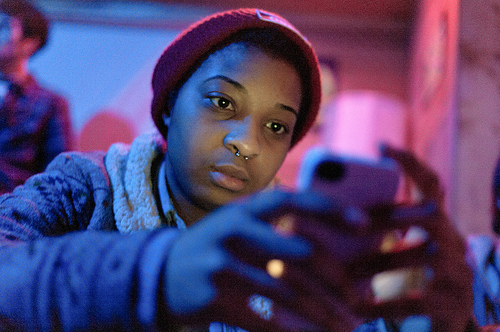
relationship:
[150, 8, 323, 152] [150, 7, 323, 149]
hat has fabric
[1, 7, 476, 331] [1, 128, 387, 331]
girl wearing a sweater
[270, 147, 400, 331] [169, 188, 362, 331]
phone in hand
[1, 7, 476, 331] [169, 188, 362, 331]
girl has a hand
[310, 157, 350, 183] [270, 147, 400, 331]
lens on back of phone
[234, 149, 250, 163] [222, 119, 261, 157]
ring in nose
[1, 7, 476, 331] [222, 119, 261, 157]
girl has a nose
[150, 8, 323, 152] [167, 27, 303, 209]
hat on head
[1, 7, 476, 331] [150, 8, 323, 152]
girl wearing a hat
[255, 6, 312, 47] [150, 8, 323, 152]
label on top of hat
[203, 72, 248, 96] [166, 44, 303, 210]
eyebrow on face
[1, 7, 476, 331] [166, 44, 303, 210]
girl has a face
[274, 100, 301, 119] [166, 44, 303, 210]
eyebrow on face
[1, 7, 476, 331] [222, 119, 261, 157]
person has a nose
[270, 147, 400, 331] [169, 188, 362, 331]
cell phone in hand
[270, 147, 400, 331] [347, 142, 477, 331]
cell phone in hand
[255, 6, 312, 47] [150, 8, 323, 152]
patch on top of cap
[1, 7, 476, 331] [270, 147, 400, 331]
student with a cell phone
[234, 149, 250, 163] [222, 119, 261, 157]
earring in nose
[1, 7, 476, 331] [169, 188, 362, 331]
kid has a hand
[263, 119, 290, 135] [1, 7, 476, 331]
eye of a kid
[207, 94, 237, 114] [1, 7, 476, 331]
eye of a kid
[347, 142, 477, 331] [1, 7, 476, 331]
hand of kid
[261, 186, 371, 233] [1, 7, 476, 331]
finger of kid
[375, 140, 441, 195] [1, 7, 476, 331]
finger of kid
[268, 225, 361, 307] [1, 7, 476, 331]
finger of kid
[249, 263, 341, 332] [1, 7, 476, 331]
finger of kid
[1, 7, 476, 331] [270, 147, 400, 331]
child holding phone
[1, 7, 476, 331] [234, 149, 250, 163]
child has a nose ring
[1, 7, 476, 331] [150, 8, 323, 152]
child wearing a hat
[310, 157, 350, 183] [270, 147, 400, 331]
camera on back of phone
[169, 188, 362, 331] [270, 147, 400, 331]
hand on phone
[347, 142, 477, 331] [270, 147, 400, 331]
hand on phone